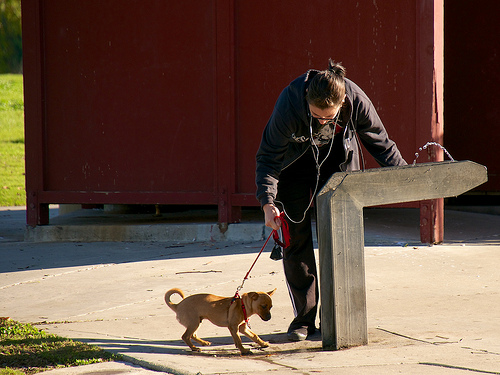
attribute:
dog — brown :
[163, 281, 283, 350]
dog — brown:
[161, 285, 274, 357]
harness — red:
[234, 269, 256, 321]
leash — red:
[224, 209, 292, 329]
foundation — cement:
[30, 220, 320, 247]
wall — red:
[41, 1, 424, 208]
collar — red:
[235, 298, 252, 323]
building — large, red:
[21, 17, 451, 243]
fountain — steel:
[413, 137, 458, 165]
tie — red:
[266, 216, 287, 240]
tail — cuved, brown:
[163, 288, 180, 308]